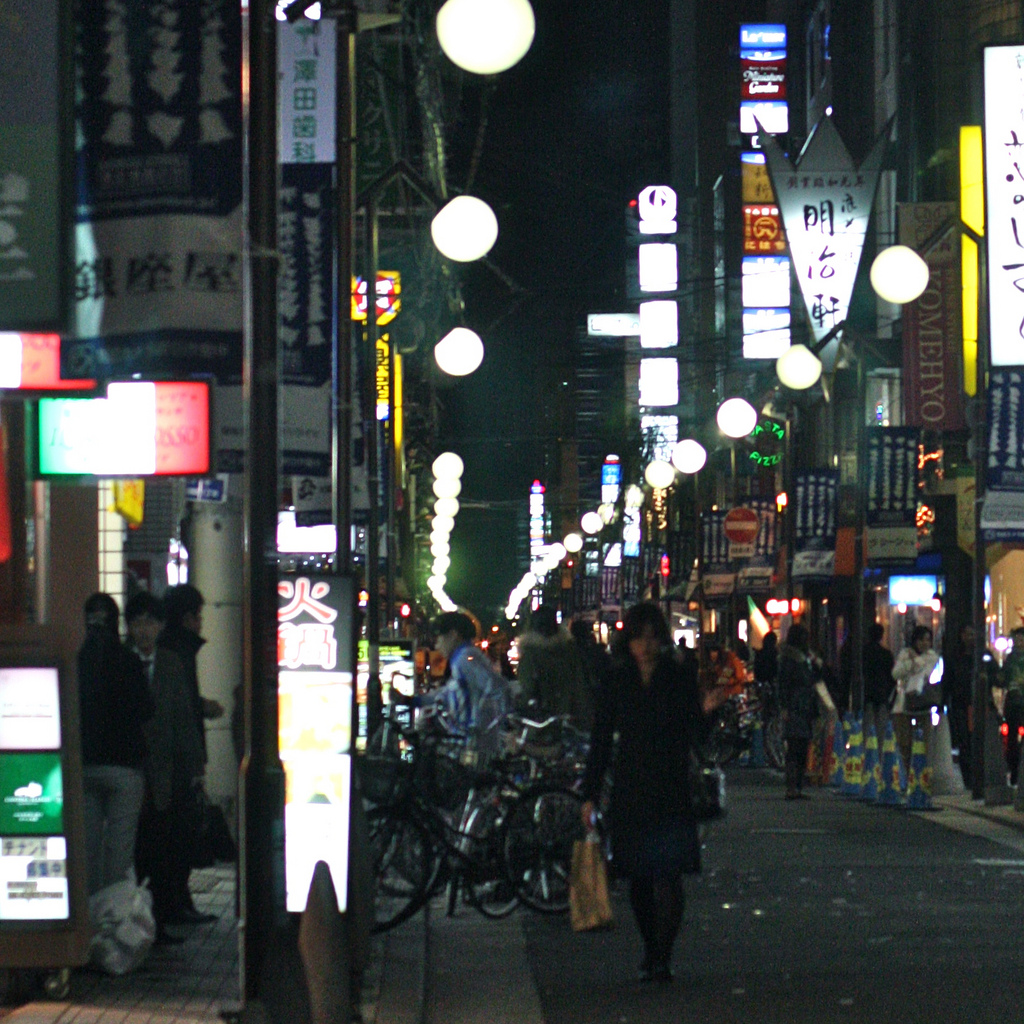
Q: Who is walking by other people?
A: Woman.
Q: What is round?
A: Lamps.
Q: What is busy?
A: Downtown street.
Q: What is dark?
A: The street.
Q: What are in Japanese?
A: Signs.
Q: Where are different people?
A: In the picture.